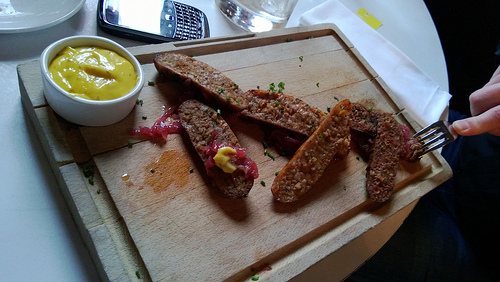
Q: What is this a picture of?
A: Food.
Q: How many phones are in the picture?
A: One.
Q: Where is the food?
A: On a cutting board.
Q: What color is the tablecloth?
A: White.